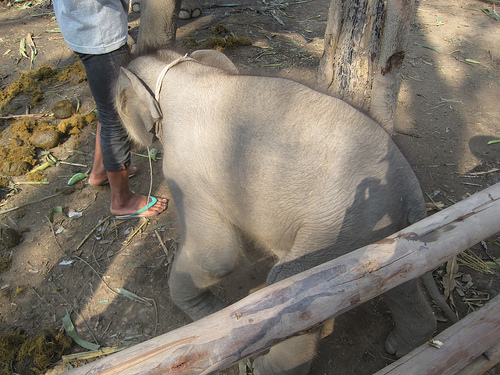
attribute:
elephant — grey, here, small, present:
[114, 48, 463, 358]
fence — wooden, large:
[53, 181, 500, 374]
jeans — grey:
[74, 44, 132, 170]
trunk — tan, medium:
[318, 0, 420, 137]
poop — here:
[1, 59, 99, 197]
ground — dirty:
[1, 0, 499, 374]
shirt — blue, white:
[52, 0, 130, 54]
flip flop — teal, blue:
[117, 196, 158, 218]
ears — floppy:
[113, 66, 165, 147]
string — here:
[153, 56, 197, 140]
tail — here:
[408, 187, 461, 325]